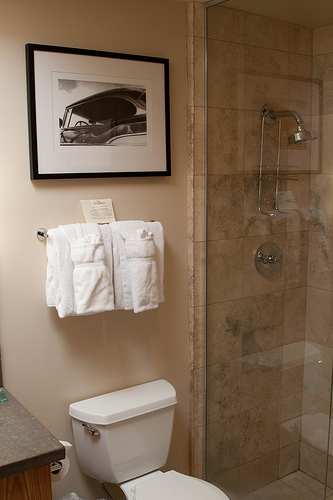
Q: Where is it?
A: This is at the bathroom.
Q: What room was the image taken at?
A: It was taken at the bathroom.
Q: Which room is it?
A: It is a bathroom.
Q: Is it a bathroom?
A: Yes, it is a bathroom.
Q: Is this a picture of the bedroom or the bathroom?
A: It is showing the bathroom.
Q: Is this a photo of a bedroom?
A: No, the picture is showing a bathroom.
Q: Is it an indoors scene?
A: Yes, it is indoors.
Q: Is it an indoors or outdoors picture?
A: It is indoors.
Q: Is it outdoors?
A: No, it is indoors.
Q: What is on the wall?
A: The picture is on the wall.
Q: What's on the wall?
A: The picture is on the wall.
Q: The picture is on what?
A: The picture is on the wall.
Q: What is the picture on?
A: The picture is on the wall.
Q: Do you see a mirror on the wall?
A: No, there is a picture on the wall.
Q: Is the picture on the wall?
A: Yes, the picture is on the wall.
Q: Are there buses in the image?
A: No, there are no buses.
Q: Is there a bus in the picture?
A: No, there are no buses.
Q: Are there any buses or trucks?
A: No, there are no buses or trucks.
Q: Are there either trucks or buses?
A: No, there are no buses or trucks.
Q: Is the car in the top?
A: Yes, the car is in the top of the image.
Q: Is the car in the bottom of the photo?
A: No, the car is in the top of the image.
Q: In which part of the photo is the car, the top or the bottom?
A: The car is in the top of the image.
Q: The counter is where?
A: The counter is in the bathroom.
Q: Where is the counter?
A: The counter is in the bathroom.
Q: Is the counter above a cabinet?
A: Yes, the counter is above a cabinet.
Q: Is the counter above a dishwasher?
A: No, the counter is above a cabinet.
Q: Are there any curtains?
A: No, there are no curtains.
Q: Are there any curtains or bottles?
A: No, there are no curtains or bottles.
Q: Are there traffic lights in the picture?
A: No, there are no traffic lights.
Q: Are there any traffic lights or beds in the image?
A: No, there are no traffic lights or beds.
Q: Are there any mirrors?
A: No, there are no mirrors.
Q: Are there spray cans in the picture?
A: No, there are no spray cans.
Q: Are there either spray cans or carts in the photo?
A: No, there are no spray cans or carts.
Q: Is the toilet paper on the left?
A: Yes, the toilet paper is on the left of the image.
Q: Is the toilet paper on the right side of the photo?
A: No, the toilet paper is on the left of the image.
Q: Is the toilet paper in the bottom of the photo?
A: Yes, the toilet paper is in the bottom of the image.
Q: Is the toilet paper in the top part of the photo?
A: No, the toilet paper is in the bottom of the image.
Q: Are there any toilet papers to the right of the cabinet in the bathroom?
A: Yes, there is a toilet paper to the right of the cabinet.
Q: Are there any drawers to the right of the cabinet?
A: No, there is a toilet paper to the right of the cabinet.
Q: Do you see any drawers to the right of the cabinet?
A: No, there is a toilet paper to the right of the cabinet.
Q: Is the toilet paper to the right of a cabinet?
A: Yes, the toilet paper is to the right of a cabinet.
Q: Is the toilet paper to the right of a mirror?
A: No, the toilet paper is to the right of a cabinet.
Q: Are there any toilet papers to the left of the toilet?
A: Yes, there is a toilet paper to the left of the toilet.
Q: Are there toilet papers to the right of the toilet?
A: No, the toilet paper is to the left of the toilet.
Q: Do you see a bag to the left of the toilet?
A: No, there is a toilet paper to the left of the toilet.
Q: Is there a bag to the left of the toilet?
A: No, there is a toilet paper to the left of the toilet.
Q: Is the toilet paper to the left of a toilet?
A: Yes, the toilet paper is to the left of a toilet.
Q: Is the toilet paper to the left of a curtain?
A: No, the toilet paper is to the left of a toilet.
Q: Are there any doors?
A: Yes, there is a door.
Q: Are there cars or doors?
A: Yes, there is a door.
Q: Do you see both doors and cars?
A: Yes, there are both a door and a car.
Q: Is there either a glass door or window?
A: Yes, there is a glass door.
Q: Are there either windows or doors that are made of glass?
A: Yes, the door is made of glass.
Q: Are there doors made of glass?
A: Yes, there is a door that is made of glass.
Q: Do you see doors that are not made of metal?
A: Yes, there is a door that is made of glass.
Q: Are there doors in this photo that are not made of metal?
A: Yes, there is a door that is made of glass.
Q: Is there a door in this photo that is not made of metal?
A: Yes, there is a door that is made of glass.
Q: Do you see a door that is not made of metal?
A: Yes, there is a door that is made of glass.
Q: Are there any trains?
A: No, there are no trains.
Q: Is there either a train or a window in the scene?
A: No, there are no trains or windows.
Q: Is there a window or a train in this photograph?
A: No, there are no trains or windows.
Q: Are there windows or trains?
A: No, there are no trains or windows.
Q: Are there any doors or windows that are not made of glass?
A: No, there is a door but it is made of glass.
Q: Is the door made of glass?
A: Yes, the door is made of glass.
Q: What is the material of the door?
A: The door is made of glass.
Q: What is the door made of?
A: The door is made of glass.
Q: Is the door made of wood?
A: No, the door is made of glass.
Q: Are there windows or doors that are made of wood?
A: No, there is a door but it is made of glass.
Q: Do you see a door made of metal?
A: No, there is a door but it is made of glass.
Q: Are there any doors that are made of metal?
A: No, there is a door but it is made of glass.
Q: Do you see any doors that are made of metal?
A: No, there is a door but it is made of glass.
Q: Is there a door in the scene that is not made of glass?
A: No, there is a door but it is made of glass.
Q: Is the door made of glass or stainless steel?
A: The door is made of glass.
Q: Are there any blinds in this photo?
A: No, there are no blinds.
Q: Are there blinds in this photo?
A: No, there are no blinds.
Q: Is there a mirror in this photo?
A: No, there are no mirrors.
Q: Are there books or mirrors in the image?
A: No, there are no mirrors or books.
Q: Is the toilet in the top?
A: No, the toilet is in the bottom of the image.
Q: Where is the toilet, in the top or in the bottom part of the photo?
A: The toilet is in the bottom of the image.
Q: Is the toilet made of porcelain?
A: Yes, the toilet is made of porcelain.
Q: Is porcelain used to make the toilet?
A: Yes, the toilet is made of porcelain.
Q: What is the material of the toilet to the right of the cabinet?
A: The toilet is made of porcelain.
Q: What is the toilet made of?
A: The toilet is made of porcelain.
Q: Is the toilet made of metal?
A: No, the toilet is made of porcelain.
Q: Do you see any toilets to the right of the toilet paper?
A: Yes, there is a toilet to the right of the toilet paper.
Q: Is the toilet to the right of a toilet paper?
A: Yes, the toilet is to the right of a toilet paper.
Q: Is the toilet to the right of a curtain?
A: No, the toilet is to the right of a toilet paper.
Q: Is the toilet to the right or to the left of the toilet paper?
A: The toilet is to the right of the toilet paper.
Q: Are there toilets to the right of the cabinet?
A: Yes, there is a toilet to the right of the cabinet.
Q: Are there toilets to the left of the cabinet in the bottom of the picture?
A: No, the toilet is to the right of the cabinet.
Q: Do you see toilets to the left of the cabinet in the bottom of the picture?
A: No, the toilet is to the right of the cabinet.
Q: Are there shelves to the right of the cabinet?
A: No, there is a toilet to the right of the cabinet.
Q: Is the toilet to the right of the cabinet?
A: Yes, the toilet is to the right of the cabinet.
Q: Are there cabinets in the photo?
A: Yes, there is a cabinet.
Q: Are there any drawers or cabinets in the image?
A: Yes, there is a cabinet.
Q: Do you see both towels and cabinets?
A: Yes, there are both a cabinet and a towel.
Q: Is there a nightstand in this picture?
A: No, there are no nightstands.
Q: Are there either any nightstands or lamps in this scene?
A: No, there are no nightstands or lamps.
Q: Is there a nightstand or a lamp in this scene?
A: No, there are no nightstands or lamps.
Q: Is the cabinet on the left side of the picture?
A: Yes, the cabinet is on the left of the image.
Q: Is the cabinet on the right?
A: No, the cabinet is on the left of the image.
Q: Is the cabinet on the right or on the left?
A: The cabinet is on the left of the image.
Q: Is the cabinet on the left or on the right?
A: The cabinet is on the left of the image.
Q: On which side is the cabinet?
A: The cabinet is on the left of the image.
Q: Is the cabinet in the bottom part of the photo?
A: Yes, the cabinet is in the bottom of the image.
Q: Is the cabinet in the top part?
A: No, the cabinet is in the bottom of the image.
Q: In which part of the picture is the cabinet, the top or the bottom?
A: The cabinet is in the bottom of the image.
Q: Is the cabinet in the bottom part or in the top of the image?
A: The cabinet is in the bottom of the image.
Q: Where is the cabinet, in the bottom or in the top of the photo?
A: The cabinet is in the bottom of the image.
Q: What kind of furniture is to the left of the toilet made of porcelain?
A: The piece of furniture is a cabinet.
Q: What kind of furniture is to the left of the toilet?
A: The piece of furniture is a cabinet.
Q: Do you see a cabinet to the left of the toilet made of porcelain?
A: Yes, there is a cabinet to the left of the toilet.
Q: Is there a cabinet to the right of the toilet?
A: No, the cabinet is to the left of the toilet.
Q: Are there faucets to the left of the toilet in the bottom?
A: No, there is a cabinet to the left of the toilet.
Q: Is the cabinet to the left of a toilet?
A: Yes, the cabinet is to the left of a toilet.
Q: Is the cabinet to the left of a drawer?
A: No, the cabinet is to the left of a toilet.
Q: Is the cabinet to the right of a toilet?
A: No, the cabinet is to the left of a toilet.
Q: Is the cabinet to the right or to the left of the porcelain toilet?
A: The cabinet is to the left of the toilet.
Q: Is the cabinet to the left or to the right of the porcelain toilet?
A: The cabinet is to the left of the toilet.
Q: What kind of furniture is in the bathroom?
A: The piece of furniture is a cabinet.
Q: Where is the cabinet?
A: The cabinet is in the bathroom.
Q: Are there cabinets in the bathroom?
A: Yes, there is a cabinet in the bathroom.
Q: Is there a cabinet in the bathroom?
A: Yes, there is a cabinet in the bathroom.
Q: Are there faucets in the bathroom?
A: No, there is a cabinet in the bathroom.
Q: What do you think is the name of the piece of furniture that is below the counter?
A: The piece of furniture is a cabinet.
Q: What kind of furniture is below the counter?
A: The piece of furniture is a cabinet.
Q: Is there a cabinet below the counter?
A: Yes, there is a cabinet below the counter.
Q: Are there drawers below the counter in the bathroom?
A: No, there is a cabinet below the counter.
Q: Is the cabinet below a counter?
A: Yes, the cabinet is below a counter.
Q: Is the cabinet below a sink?
A: No, the cabinet is below a counter.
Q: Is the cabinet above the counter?
A: No, the cabinet is below the counter.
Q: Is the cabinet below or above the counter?
A: The cabinet is below the counter.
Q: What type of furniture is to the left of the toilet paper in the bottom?
A: The piece of furniture is a cabinet.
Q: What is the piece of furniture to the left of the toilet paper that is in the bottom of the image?
A: The piece of furniture is a cabinet.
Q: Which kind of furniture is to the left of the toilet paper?
A: The piece of furniture is a cabinet.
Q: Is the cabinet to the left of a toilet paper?
A: Yes, the cabinet is to the left of a toilet paper.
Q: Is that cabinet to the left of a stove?
A: No, the cabinet is to the left of a toilet paper.